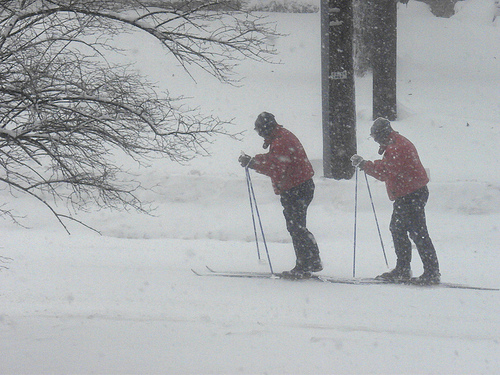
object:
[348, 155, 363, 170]
glove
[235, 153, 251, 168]
glove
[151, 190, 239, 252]
snow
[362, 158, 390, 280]
ski poles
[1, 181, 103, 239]
branch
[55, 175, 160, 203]
branch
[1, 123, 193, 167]
branch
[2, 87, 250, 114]
branch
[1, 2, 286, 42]
branch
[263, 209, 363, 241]
snow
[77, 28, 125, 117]
snow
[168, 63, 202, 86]
branches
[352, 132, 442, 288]
outfits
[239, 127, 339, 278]
outfits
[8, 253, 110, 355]
snow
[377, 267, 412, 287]
feet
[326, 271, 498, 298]
skis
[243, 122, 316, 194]
red jacket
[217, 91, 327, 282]
man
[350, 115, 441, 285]
man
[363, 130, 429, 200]
red jacket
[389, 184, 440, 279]
black pants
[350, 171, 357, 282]
poles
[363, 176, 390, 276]
poles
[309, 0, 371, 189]
pole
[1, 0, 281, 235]
bare trees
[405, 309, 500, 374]
snow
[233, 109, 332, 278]
leaning forward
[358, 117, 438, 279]
leaning forward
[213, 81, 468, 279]
snow covering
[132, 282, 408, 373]
snow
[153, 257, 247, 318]
snow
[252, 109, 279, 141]
head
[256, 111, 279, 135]
cap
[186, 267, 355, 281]
ski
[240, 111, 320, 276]
ski gear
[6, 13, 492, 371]
ground